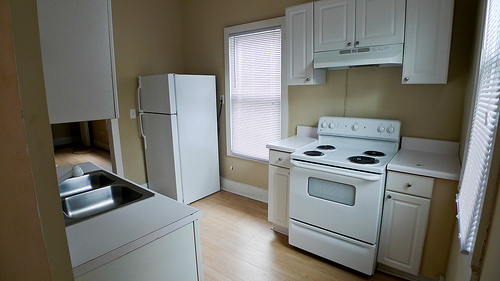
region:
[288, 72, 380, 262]
White stove and oven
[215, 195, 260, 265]
Light colored hard wood floors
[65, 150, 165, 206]
A stainless steel sink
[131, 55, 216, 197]
A white fridge and freezer combo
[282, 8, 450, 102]
White cabinets with chrome knobs and beige walls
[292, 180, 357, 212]
Oven has an oven window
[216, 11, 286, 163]
Window with blinds covering it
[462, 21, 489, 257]
Mini-blinds covering window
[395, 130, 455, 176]
White counter tops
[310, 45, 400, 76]
A white hood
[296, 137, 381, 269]
the oven is white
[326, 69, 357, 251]
the oven is white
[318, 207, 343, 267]
the oven is white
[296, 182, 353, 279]
the oven is white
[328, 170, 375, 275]
the oven is white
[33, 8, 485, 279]
a kitchen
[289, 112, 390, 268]
a white stove with four burners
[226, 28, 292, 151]
a window with white blinds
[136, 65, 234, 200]
a refrigerator in the corner of a kitchen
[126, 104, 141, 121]
a white light switch on the wall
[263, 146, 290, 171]
a kitchen drawer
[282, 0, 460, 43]
white cabinets over the stove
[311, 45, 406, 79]
under cabinet range hood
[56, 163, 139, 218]
a double sink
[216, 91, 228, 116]
outlet on the wall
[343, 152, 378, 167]
a black burner on the stove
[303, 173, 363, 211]
a window on the oven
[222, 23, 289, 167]
a window on the wall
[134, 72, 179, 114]
the door of the freezer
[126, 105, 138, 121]
a white light switch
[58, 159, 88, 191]
a white faucet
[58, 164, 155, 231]
a metal sink on the counter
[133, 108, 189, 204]
the door of a refrigerator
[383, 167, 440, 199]
a white wooden drawer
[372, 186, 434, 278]
a white cabinet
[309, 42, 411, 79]
stove vent under the cabinet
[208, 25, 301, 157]
blinds on the window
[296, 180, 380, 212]
glass on the oven door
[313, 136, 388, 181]
four burners on the stove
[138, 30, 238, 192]
refrigerator in the corner of the kitchen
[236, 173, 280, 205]
trim is white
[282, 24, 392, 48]
cabinets are white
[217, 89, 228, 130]
refrigerator plug in outlet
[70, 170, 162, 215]
sink is stainless steel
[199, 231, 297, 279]
floors are wood